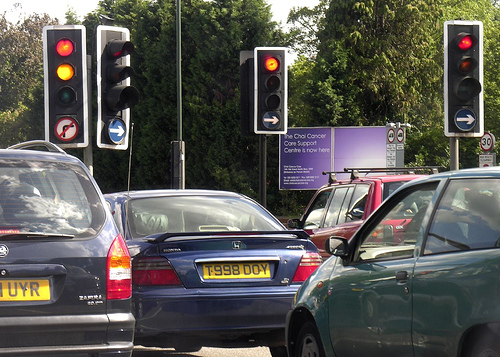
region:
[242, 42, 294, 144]
stop light with red light lit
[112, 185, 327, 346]
rear end of a blue car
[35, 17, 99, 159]
signal light with red and yellow light lit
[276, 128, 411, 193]
blue street sign with white letters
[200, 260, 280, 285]
yellow license plate with black letters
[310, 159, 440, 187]
black luggage rack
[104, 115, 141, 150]
arrow with blue back ground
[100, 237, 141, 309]
tail light with orange,red and white glass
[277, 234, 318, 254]
silver logo on back of car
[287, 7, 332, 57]
tree branches with green leafs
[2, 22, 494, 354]
four vehicles waiting at a traffic light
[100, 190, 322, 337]
a blue car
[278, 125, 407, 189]
a purple sign for a cancer support center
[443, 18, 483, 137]
a traffic light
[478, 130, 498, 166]
a speed limit sign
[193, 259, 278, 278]
a yellow license plate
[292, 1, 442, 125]
a group of trees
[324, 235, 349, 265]
a rearview mirror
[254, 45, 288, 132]
a traffic light with an arrow pointing right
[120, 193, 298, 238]
the rear window of a car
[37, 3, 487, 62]
Red traffic lights.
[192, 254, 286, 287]
License plate.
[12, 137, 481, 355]
Traffic waiting for the lights to change.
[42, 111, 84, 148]
No right turn, sign.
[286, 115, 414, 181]
Cancer center sign.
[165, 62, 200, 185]
Large pole.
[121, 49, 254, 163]
Trees behind the traffic lights.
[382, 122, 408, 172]
Many traffic signs.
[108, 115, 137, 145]
Right turn sign.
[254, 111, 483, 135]
Right turn signs.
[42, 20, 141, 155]
two traffic signals next to each other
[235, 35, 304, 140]
traffic signal with white outline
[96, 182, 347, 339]
blue car with yellow license plate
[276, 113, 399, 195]
purple sign with white writing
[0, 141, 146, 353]
black van of European orign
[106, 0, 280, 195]
tall trees near a street intersection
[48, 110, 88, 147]
no right turn sign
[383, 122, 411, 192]
white traffic signs with black lettering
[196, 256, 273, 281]
yellow license plate with black writing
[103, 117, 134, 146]
round traffic sign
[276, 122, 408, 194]
blue sign on the side of the roadway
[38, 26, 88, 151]
traffic light showing red and yellow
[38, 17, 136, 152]
two adjacent traffic signals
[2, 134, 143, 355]
half of a blue passenger van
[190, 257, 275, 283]
license plate on a blue honda car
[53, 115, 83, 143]
do not turn sign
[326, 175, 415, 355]
driver's door of a green van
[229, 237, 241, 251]
honda emblem on a blue car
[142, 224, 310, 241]
spoiler on a blue car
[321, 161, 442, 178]
luggage rack on a red van